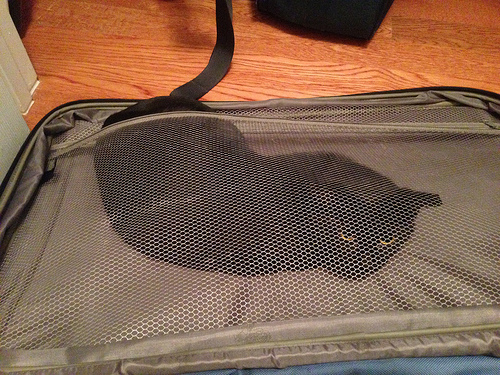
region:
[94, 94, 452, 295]
this is a cat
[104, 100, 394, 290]
the cat is black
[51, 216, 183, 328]
this is a flap of a bag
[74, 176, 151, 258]
this is a flap of a bag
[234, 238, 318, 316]
this is a flap of a bag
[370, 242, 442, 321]
this is a flap of a bag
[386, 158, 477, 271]
this is a flap of a bag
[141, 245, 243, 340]
this is a flap of a bag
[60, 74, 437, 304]
cat inside the pocket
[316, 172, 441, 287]
head of a cat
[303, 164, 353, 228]
ear of a cat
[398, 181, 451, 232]
ear of a cat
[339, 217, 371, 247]
eye of a cat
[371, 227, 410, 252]
eye of a cat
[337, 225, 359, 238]
an eye of a cat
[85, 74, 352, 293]
body of a cat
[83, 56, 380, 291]
a body of a cat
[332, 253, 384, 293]
mouth of a cat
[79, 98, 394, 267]
cat is in luggage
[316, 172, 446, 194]
cat has black ears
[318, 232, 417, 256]
cat has brown eyes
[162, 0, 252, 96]
black strap behind cat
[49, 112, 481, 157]
grey zipper on mesh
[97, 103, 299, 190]
black fur on cat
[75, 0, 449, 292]
Cat under the netting.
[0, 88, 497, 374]
Luggage on the floor.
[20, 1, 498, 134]
Brown hardwood floor in the background.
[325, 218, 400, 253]
yellow eyes on the pouch.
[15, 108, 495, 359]
Pouch in the bag.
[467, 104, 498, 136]
Zipper on the bag.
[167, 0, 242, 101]
Black tail on the cat.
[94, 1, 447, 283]
Black hair on the cat.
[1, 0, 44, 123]
White wood framing in the background.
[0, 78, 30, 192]
White wall beside the luggage.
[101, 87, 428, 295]
black cat in luggage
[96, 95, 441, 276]
the cat is black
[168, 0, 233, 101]
the strap is black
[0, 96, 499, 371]
the black cat in the luggage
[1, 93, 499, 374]
the cat in the large mesh pocket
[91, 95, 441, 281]
the black cat has yellow eyes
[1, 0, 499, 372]
the luggage on the wooden floor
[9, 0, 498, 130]
the wood floor is brown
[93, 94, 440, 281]
the cat has opened eyes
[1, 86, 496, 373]
the zipper is opened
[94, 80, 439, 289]
cat in bag compartment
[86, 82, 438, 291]
cat in bag compartment